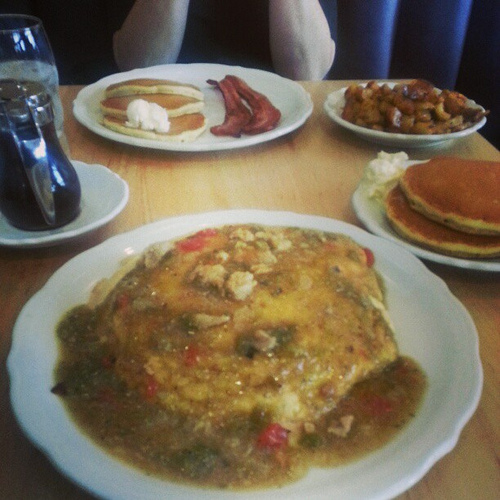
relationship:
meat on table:
[209, 64, 293, 139] [2, 76, 499, 498]